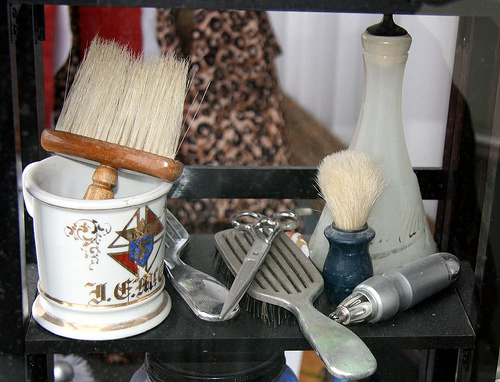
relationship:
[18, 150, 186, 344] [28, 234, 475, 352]
mug sitting on shelf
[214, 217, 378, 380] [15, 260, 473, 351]
brush lying on shelf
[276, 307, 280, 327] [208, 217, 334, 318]
bristle attached to brush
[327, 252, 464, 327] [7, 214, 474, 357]
hair trimmer lying on shelf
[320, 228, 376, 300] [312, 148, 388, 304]
handle attached to brush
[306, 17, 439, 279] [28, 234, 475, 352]
bottle sitting on shelf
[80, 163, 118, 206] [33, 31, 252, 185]
handle attached to brush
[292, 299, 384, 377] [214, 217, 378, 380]
handle attached to brush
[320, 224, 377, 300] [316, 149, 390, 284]
handle attached to brush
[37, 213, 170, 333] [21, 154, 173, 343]
gold writing painted on mug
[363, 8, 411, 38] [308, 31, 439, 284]
black top topping bottle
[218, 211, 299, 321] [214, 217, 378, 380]
scissor lying on brush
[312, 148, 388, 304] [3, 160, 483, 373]
brush sitting on table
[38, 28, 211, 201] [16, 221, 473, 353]
brush sitting on table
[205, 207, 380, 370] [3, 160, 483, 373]
brush lying on table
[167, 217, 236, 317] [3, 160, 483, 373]
fork lying on table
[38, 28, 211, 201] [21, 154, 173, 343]
brush sitting in mug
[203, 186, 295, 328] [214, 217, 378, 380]
scissor lying on top of brush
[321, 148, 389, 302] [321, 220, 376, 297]
brush has handle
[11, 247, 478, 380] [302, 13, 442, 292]
table has lamp